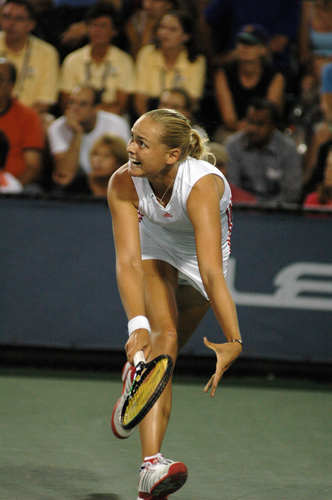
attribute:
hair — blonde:
[129, 97, 218, 184]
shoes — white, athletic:
[92, 361, 190, 491]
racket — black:
[93, 339, 185, 430]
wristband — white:
[110, 311, 157, 343]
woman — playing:
[73, 103, 256, 495]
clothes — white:
[119, 170, 241, 308]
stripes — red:
[224, 187, 233, 273]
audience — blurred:
[25, 18, 296, 169]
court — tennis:
[10, 350, 324, 499]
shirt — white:
[51, 115, 124, 164]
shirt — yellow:
[141, 43, 208, 101]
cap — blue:
[234, 24, 273, 44]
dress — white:
[122, 235, 233, 309]